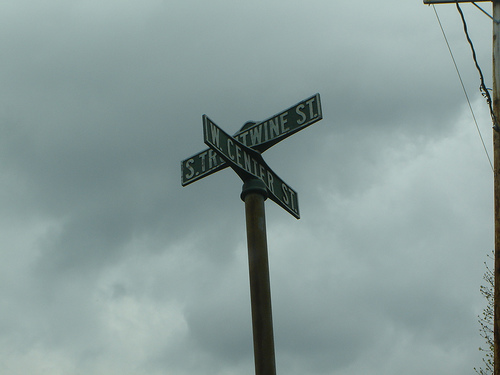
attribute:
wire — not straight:
[433, 15, 449, 59]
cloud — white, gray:
[355, 113, 407, 160]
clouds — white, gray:
[1, 3, 486, 368]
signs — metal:
[139, 85, 374, 239]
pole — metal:
[219, 200, 306, 344]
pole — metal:
[226, 132, 287, 373]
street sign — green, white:
[199, 112, 301, 222]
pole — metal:
[241, 192, 279, 369]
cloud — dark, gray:
[323, 7, 485, 175]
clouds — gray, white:
[408, 130, 477, 282]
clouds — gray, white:
[95, 5, 385, 140]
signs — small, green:
[175, 91, 323, 223]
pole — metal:
[246, 193, 279, 373]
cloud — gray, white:
[10, 8, 145, 128]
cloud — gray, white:
[42, 66, 145, 138]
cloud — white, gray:
[28, 41, 151, 212]